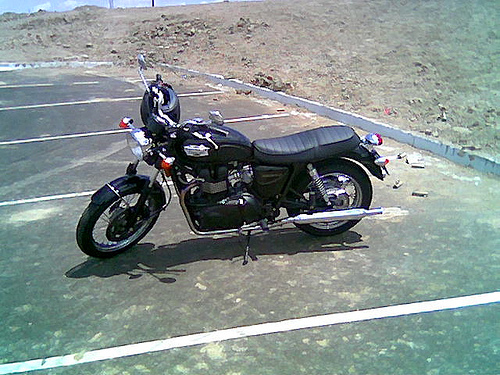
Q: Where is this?
A: This is at the parking lot.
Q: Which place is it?
A: It is a parking lot.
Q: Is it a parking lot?
A: Yes, it is a parking lot.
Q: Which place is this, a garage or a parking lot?
A: It is a parking lot.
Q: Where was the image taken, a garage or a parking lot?
A: It was taken at a parking lot.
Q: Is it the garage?
A: No, it is the parking lot.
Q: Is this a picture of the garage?
A: No, the picture is showing the parking lot.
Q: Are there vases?
A: No, there are no vases.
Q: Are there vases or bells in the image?
A: No, there are no vases or bells.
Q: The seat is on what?
A: The seat is on the bike.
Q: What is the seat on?
A: The seat is on the bike.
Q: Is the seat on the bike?
A: Yes, the seat is on the bike.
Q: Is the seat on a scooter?
A: No, the seat is on the bike.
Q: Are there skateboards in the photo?
A: No, there are no skateboards.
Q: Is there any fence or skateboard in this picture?
A: No, there are no skateboards or fences.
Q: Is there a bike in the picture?
A: Yes, there is a bike.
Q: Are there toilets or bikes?
A: Yes, there is a bike.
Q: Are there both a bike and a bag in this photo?
A: No, there is a bike but no bags.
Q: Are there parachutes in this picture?
A: No, there are no parachutes.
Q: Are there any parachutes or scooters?
A: No, there are no parachutes or scooters.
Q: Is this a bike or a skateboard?
A: This is a bike.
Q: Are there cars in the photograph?
A: No, there are no cars.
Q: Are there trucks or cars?
A: No, there are no cars or trucks.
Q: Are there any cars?
A: No, there are no cars.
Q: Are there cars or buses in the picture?
A: No, there are no cars or buses.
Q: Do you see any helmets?
A: Yes, there is a helmet.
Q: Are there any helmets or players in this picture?
A: Yes, there is a helmet.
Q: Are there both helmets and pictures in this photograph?
A: No, there is a helmet but no pictures.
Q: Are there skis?
A: No, there are no skis.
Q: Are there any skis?
A: No, there are no skis.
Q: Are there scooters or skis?
A: No, there are no skis or scooters.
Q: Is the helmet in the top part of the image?
A: Yes, the helmet is in the top of the image.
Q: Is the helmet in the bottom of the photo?
A: No, the helmet is in the top of the image.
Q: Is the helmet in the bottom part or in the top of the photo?
A: The helmet is in the top of the image.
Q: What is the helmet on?
A: The helmet is on the bike.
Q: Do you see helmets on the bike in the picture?
A: Yes, there is a helmet on the bike.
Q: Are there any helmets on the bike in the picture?
A: Yes, there is a helmet on the bike.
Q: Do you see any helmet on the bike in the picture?
A: Yes, there is a helmet on the bike.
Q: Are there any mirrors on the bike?
A: No, there is a helmet on the bike.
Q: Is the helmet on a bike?
A: Yes, the helmet is on a bike.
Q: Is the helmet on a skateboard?
A: No, the helmet is on a bike.